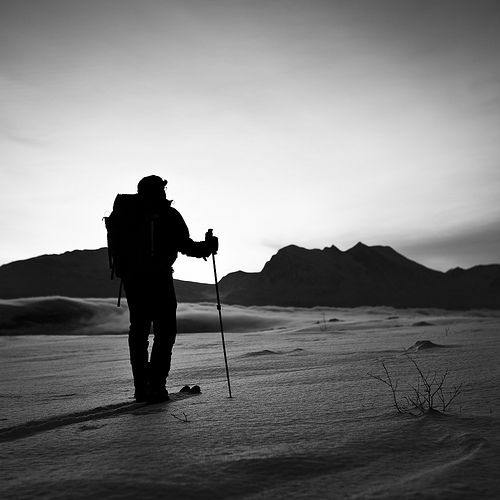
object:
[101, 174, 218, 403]
man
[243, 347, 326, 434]
snow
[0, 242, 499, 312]
mountains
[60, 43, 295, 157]
sky